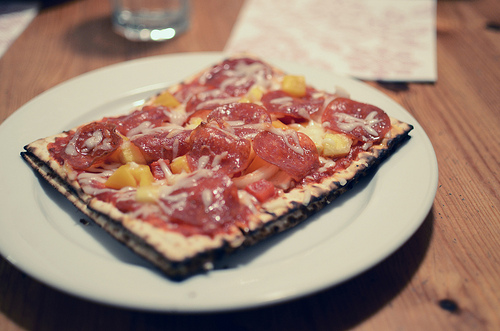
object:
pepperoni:
[48, 52, 383, 214]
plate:
[96, 75, 132, 100]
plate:
[0, 54, 436, 314]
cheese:
[106, 160, 155, 190]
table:
[38, 5, 498, 321]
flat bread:
[15, 41, 419, 288]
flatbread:
[19, 43, 417, 289]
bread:
[340, 133, 400, 192]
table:
[448, 187, 492, 267]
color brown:
[443, 94, 493, 160]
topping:
[185, 120, 253, 175]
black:
[291, 200, 297, 209]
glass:
[106, 0, 193, 44]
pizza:
[31, 62, 421, 265]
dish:
[26, 64, 403, 299]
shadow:
[220, 262, 410, 329]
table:
[437, 15, 484, 308]